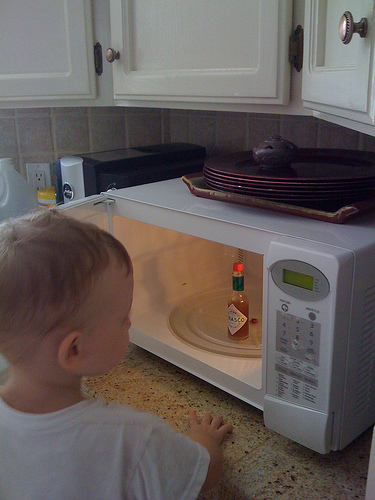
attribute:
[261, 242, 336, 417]
control panel — microwave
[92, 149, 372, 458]
microwave — turn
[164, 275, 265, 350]
plate — microwave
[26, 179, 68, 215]
container — yellow, white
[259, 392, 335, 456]
button — door, release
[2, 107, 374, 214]
backsplash — tiled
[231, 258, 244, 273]
lid — red 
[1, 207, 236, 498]
child — young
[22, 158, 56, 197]
outlet — white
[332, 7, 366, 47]
knob — decorative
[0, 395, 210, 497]
shirt — white, tee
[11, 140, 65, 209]
outlet — white, electrical, wall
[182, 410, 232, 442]
hand — little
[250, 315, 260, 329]
residue — food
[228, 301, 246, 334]
sauce — Tabasco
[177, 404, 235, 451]
hand — child's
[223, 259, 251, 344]
bottle — small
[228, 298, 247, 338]
sauce — Tabasco